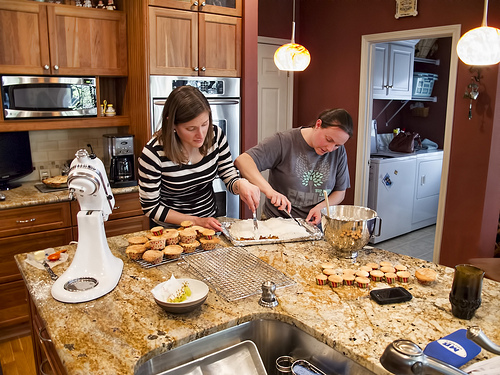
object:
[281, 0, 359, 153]
wall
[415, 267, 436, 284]
cupcakes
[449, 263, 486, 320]
dark glass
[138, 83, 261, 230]
woman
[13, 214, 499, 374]
counter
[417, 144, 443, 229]
dryer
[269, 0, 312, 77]
lamp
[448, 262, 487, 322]
cup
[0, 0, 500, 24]
ceiling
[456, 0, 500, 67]
light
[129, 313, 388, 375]
sink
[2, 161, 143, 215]
counter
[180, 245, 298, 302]
rack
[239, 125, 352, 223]
shirt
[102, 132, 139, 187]
coffee maker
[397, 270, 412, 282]
cupcakes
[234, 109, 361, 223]
woman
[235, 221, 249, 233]
iced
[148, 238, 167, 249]
muffin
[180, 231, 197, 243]
muffin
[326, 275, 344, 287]
muffin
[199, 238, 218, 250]
muffin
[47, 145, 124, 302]
mixer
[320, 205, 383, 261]
bowl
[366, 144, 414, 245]
washer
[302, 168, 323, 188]
green leaves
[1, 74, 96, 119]
microwave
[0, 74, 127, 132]
shelf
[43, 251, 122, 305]
base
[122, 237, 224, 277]
rack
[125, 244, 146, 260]
cupcakes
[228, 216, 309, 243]
cake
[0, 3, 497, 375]
kitchen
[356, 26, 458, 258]
laundry room